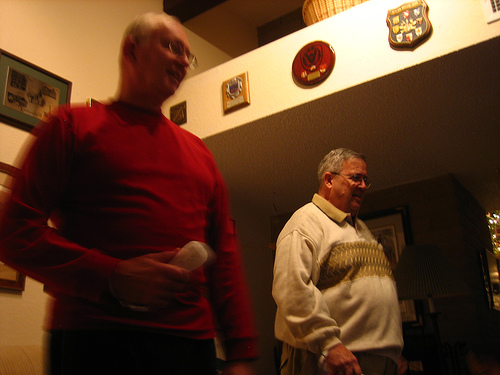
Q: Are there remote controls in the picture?
A: Yes, there is a remote control.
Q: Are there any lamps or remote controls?
A: Yes, there is a remote control.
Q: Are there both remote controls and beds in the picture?
A: No, there is a remote control but no beds.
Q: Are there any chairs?
A: No, there are no chairs.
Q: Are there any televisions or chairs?
A: No, there are no chairs or televisions.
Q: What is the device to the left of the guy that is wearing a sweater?
A: The device is a remote control.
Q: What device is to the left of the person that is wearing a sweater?
A: The device is a remote control.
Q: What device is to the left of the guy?
A: The device is a remote control.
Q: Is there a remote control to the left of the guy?
A: Yes, there is a remote control to the left of the guy.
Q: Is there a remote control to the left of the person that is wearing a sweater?
A: Yes, there is a remote control to the left of the guy.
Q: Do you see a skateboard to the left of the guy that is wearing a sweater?
A: No, there is a remote control to the left of the guy.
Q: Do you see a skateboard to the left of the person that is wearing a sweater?
A: No, there is a remote control to the left of the guy.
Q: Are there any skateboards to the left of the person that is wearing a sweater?
A: No, there is a remote control to the left of the guy.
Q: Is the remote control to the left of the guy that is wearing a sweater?
A: Yes, the remote control is to the left of the guy.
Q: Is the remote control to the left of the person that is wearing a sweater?
A: Yes, the remote control is to the left of the guy.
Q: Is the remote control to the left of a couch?
A: No, the remote control is to the left of the guy.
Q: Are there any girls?
A: No, there are no girls.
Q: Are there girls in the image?
A: No, there are no girls.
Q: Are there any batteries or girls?
A: No, there are no girls or batteries.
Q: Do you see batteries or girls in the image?
A: No, there are no girls or batteries.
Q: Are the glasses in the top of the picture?
A: Yes, the glasses are in the top of the image.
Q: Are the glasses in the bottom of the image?
A: No, the glasses are in the top of the image.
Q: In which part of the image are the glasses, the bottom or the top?
A: The glasses are in the top of the image.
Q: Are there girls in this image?
A: No, there are no girls.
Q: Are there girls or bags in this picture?
A: No, there are no girls or bags.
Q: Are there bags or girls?
A: No, there are no girls or bags.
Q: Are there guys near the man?
A: Yes, there is a guy near the man.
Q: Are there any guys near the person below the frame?
A: Yes, there is a guy near the man.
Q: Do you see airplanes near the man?
A: No, there is a guy near the man.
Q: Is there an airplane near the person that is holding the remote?
A: No, there is a guy near the man.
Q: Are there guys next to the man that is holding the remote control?
A: Yes, there is a guy next to the man.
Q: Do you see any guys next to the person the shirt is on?
A: Yes, there is a guy next to the man.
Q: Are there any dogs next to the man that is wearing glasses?
A: No, there is a guy next to the man.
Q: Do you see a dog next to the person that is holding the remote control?
A: No, there is a guy next to the man.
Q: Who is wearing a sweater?
A: The guy is wearing a sweater.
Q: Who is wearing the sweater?
A: The guy is wearing a sweater.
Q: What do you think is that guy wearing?
A: The guy is wearing a sweater.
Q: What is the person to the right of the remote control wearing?
A: The guy is wearing a sweater.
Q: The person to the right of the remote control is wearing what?
A: The guy is wearing a sweater.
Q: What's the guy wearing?
A: The guy is wearing a sweater.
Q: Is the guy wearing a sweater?
A: Yes, the guy is wearing a sweater.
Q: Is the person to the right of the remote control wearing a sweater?
A: Yes, the guy is wearing a sweater.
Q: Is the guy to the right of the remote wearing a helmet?
A: No, the guy is wearing a sweater.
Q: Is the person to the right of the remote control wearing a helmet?
A: No, the guy is wearing a sweater.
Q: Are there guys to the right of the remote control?
A: Yes, there is a guy to the right of the remote control.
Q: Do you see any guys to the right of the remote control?
A: Yes, there is a guy to the right of the remote control.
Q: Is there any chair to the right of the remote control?
A: No, there is a guy to the right of the remote control.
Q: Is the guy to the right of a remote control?
A: Yes, the guy is to the right of a remote control.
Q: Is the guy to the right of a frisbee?
A: No, the guy is to the right of a remote control.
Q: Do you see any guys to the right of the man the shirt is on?
A: Yes, there is a guy to the right of the man.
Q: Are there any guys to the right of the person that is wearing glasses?
A: Yes, there is a guy to the right of the man.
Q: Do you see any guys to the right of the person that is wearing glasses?
A: Yes, there is a guy to the right of the man.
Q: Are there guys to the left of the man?
A: No, the guy is to the right of the man.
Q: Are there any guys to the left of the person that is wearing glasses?
A: No, the guy is to the right of the man.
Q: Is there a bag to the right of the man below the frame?
A: No, there is a guy to the right of the man.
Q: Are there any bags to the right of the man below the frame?
A: No, there is a guy to the right of the man.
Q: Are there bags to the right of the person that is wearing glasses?
A: No, there is a guy to the right of the man.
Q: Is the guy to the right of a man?
A: Yes, the guy is to the right of a man.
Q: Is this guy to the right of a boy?
A: No, the guy is to the right of a man.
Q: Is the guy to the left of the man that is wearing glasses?
A: No, the guy is to the right of the man.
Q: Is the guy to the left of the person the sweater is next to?
A: No, the guy is to the right of the man.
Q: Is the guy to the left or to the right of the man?
A: The guy is to the right of the man.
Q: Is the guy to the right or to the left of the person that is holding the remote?
A: The guy is to the right of the man.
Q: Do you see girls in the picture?
A: No, there are no girls.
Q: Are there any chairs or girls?
A: No, there are no girls or chairs.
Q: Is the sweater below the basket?
A: Yes, the sweater is below the basket.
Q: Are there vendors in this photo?
A: No, there are no vendors.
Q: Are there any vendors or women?
A: No, there are no vendors or women.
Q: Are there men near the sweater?
A: Yes, there is a man near the sweater.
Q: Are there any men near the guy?
A: Yes, there is a man near the guy.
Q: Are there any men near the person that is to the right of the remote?
A: Yes, there is a man near the guy.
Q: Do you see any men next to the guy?
A: Yes, there is a man next to the guy.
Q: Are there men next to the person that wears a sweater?
A: Yes, there is a man next to the guy.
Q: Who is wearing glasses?
A: The man is wearing glasses.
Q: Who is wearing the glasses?
A: The man is wearing glasses.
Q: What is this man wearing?
A: The man is wearing glasses.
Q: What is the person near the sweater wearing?
A: The man is wearing glasses.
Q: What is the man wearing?
A: The man is wearing glasses.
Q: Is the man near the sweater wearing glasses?
A: Yes, the man is wearing glasses.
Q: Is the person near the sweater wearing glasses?
A: Yes, the man is wearing glasses.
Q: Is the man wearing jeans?
A: No, the man is wearing glasses.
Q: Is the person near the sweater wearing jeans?
A: No, the man is wearing glasses.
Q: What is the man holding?
A: The man is holding the remote.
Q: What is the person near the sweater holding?
A: The man is holding the remote.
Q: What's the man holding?
A: The man is holding the remote.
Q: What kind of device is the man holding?
A: The man is holding the remote control.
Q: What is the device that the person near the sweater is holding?
A: The device is a remote control.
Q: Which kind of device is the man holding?
A: The man is holding the remote control.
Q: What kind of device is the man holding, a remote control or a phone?
A: The man is holding a remote control.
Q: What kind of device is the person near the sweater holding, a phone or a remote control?
A: The man is holding a remote control.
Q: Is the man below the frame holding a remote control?
A: Yes, the man is holding a remote control.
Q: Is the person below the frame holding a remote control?
A: Yes, the man is holding a remote control.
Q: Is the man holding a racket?
A: No, the man is holding a remote control.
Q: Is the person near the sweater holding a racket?
A: No, the man is holding a remote control.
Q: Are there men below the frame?
A: Yes, there is a man below the frame.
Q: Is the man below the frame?
A: Yes, the man is below the frame.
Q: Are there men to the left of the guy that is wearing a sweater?
A: Yes, there is a man to the left of the guy.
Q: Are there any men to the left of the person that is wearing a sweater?
A: Yes, there is a man to the left of the guy.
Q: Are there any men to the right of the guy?
A: No, the man is to the left of the guy.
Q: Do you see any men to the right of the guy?
A: No, the man is to the left of the guy.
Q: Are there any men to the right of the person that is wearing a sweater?
A: No, the man is to the left of the guy.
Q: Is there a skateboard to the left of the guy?
A: No, there is a man to the left of the guy.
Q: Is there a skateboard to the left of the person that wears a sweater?
A: No, there is a man to the left of the guy.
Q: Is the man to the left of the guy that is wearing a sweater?
A: Yes, the man is to the left of the guy.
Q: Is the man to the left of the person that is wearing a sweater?
A: Yes, the man is to the left of the guy.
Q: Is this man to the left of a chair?
A: No, the man is to the left of the guy.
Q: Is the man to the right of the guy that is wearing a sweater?
A: No, the man is to the left of the guy.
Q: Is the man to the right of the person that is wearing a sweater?
A: No, the man is to the left of the guy.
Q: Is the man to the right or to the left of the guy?
A: The man is to the left of the guy.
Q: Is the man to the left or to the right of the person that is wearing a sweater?
A: The man is to the left of the guy.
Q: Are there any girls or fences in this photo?
A: No, there are no girls or fences.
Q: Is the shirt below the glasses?
A: Yes, the shirt is below the glasses.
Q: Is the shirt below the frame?
A: Yes, the shirt is below the frame.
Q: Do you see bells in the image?
A: No, there are no bells.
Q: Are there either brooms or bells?
A: No, there are no bells or brooms.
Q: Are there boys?
A: No, there are no boys.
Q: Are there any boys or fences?
A: No, there are no boys or fences.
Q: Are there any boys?
A: No, there are no boys.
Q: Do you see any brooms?
A: No, there are no brooms.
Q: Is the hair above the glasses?
A: Yes, the hair is above the glasses.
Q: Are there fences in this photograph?
A: No, there are no fences.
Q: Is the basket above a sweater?
A: Yes, the basket is above a sweater.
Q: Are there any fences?
A: No, there are no fences.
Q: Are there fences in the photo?
A: No, there are no fences.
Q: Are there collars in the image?
A: Yes, there is a collar.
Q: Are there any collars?
A: Yes, there is a collar.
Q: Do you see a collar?
A: Yes, there is a collar.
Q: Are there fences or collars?
A: Yes, there is a collar.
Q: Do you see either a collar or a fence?
A: Yes, there is a collar.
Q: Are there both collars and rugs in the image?
A: No, there is a collar but no rugs.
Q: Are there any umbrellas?
A: No, there are no umbrellas.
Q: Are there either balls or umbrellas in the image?
A: No, there are no umbrellas or balls.